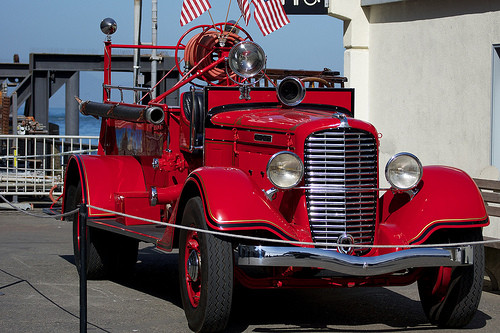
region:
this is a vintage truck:
[60, 10, 487, 306]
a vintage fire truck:
[60, 8, 487, 300]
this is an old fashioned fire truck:
[51, 15, 498, 310]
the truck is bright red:
[50, 22, 499, 327]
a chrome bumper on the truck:
[237, 234, 469, 287]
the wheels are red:
[174, 218, 216, 320]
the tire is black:
[169, 188, 258, 330]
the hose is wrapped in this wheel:
[174, 23, 264, 90]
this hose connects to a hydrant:
[66, 90, 172, 133]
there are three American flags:
[170, 1, 307, 40]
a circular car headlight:
[262, 150, 302, 187]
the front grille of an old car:
[301, 121, 373, 252]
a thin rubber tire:
[170, 195, 238, 331]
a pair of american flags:
[171, 0, 293, 36]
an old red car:
[59, 44, 486, 320]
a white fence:
[0, 138, 105, 199]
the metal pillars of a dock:
[27, 55, 82, 135]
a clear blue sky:
[0, 0, 100, 51]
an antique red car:
[61, 20, 489, 320]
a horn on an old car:
[271, 78, 311, 107]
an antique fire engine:
[59, 18, 489, 326]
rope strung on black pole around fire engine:
[1, 193, 498, 332]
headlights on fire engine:
[268, 152, 421, 197]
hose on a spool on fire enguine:
[179, 27, 245, 82]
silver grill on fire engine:
[304, 132, 374, 246]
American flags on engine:
[182, 3, 286, 34]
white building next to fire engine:
[327, 1, 499, 246]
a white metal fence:
[3, 135, 100, 206]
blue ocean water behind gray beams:
[23, 104, 106, 139]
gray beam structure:
[0, 53, 179, 135]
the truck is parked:
[60, 16, 487, 324]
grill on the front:
[307, 132, 374, 252]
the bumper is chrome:
[234, 243, 471, 273]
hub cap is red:
[185, 230, 199, 303]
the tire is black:
[182, 199, 226, 329]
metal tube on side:
[80, 102, 161, 124]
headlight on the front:
[387, 152, 421, 187]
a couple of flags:
[178, 0, 287, 37]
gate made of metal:
[1, 134, 98, 202]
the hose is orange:
[185, 30, 242, 80]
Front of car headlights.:
[256, 150, 423, 197]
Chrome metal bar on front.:
[231, 244, 471, 274]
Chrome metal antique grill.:
[301, 112, 384, 254]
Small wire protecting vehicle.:
[83, 202, 498, 269]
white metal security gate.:
[3, 133, 66, 200]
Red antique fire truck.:
[63, 19, 493, 323]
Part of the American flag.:
[243, 0, 288, 35]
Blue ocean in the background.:
[18, 98, 86, 135]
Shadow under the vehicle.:
[56, 240, 465, 330]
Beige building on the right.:
[352, 8, 489, 108]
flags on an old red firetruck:
[60, 0, 487, 321]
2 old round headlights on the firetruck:
[267, 150, 420, 193]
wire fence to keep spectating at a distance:
[1, 189, 498, 327]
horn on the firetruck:
[272, 72, 307, 107]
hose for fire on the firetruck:
[176, 25, 259, 92]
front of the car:
[151, 36, 491, 316]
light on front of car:
[240, 135, 321, 210]